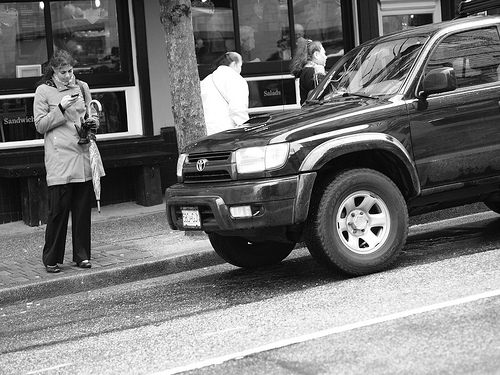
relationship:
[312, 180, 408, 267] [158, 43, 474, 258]
tire on a car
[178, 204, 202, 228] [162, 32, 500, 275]
license plate on a car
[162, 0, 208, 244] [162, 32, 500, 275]
tree next to car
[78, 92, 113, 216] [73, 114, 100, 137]
umbrella in hand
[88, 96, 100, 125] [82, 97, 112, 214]
handle for umbrella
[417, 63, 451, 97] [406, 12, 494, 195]
mirror on side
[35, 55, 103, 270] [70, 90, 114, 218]
woman holding umbrella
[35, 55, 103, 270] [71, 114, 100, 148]
woman holding glove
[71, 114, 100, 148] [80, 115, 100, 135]
glove in hand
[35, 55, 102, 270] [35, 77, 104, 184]
woman wearing a coat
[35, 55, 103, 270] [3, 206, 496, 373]
woman near street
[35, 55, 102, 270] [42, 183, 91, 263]
woman wearing pants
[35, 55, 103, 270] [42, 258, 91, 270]
woman wearing shoes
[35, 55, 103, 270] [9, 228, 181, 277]
woman on sidewalk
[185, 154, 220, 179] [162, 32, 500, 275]
logo on front car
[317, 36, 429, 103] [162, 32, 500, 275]
windshield of car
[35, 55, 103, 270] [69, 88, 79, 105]
woman of her cell phone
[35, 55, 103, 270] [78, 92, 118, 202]
woman carrying umbrella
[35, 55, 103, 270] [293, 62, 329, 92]
woman wearing coat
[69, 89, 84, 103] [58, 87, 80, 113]
cell phone in hand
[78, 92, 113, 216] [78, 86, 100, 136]
umbrella on woman's arm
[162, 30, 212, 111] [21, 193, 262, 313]
tree on sidewalk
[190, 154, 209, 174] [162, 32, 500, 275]
logo on car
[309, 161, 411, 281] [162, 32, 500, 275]
wheels on car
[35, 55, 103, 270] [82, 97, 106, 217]
woman with umbrella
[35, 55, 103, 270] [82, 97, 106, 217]
woman holding umbrella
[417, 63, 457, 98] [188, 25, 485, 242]
mirror on car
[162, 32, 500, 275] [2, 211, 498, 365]
car on road